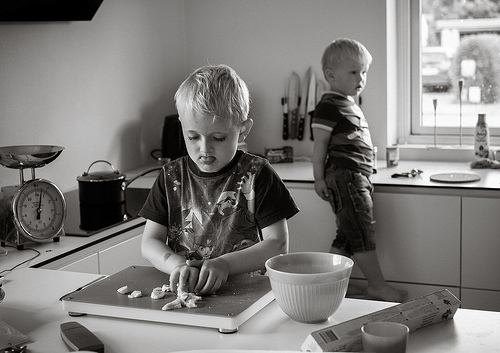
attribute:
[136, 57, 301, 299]
boy — standing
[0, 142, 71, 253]
scale — silver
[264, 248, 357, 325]
bowl — light-colored, white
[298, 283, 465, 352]
box — pictured, long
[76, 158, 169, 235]
pot — dark lidded, black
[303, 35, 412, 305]
boy — standing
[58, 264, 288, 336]
chopping board — pictured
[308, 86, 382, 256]
clothes — dark